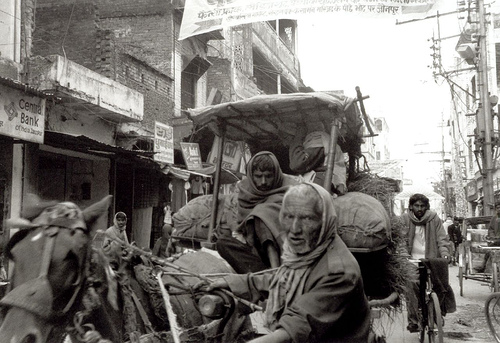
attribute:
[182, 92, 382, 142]
canopy — wood, flimsy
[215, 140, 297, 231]
man — ill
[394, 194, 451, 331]
man — wearing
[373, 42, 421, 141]
sky — clear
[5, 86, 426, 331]
horse cart — paper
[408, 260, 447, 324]
pants — long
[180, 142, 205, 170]
sign — lopsided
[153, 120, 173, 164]
sign — second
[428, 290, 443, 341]
tire — rubber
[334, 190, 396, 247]
sacks — large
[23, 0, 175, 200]
building — large, brick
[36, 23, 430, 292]
buildings — old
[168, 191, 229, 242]
bag — supplies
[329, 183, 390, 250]
bag — supplies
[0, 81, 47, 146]
sign — bank, rectangular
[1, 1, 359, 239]
building — old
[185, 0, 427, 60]
banner — large, white, hanging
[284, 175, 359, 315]
man — elder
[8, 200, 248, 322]
horse — brown